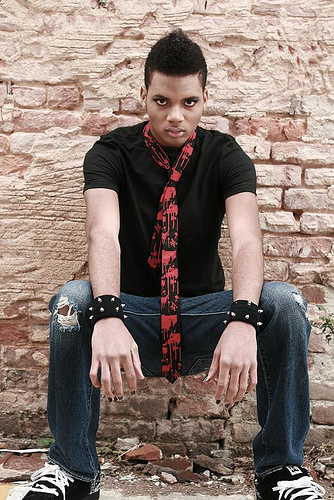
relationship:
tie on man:
[146, 118, 191, 381] [16, 27, 325, 498]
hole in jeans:
[50, 292, 81, 330] [51, 277, 316, 478]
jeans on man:
[51, 277, 316, 478] [16, 27, 325, 498]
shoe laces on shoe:
[23, 462, 70, 499] [21, 456, 98, 498]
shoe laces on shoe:
[270, 475, 328, 498] [251, 459, 326, 499]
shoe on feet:
[252, 463, 320, 498] [246, 458, 331, 498]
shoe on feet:
[21, 456, 98, 498] [21, 460, 95, 498]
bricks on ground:
[115, 437, 234, 498] [102, 469, 249, 498]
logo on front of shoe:
[288, 460, 303, 472] [251, 459, 326, 499]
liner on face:
[180, 96, 196, 107] [142, 65, 201, 142]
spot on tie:
[158, 361, 169, 374] [142, 133, 183, 383]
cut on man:
[149, 29, 202, 75] [49, 27, 318, 498]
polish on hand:
[211, 392, 243, 407] [210, 317, 262, 415]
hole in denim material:
[50, 292, 81, 330] [48, 363, 68, 422]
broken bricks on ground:
[122, 429, 235, 476] [103, 435, 252, 470]